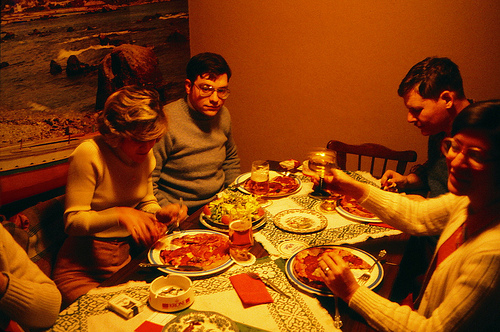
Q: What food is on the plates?
A: Pizza.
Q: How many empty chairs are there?
A: 1.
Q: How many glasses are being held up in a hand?
A: 1.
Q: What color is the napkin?
A: Red.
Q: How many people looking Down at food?
A: 2.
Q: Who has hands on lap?
A: Man in glasses.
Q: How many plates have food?
A: 5.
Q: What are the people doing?
A: Dining.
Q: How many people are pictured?
A: 5.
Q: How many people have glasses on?
A: Two.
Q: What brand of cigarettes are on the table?
A: Marlboro.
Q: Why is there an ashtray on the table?
A: For cigarette ashes/butts.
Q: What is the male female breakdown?
A: Two males, two females.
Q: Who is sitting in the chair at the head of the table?
A: No one.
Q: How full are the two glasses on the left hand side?
A: Three quarters.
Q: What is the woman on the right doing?
A: Raising her glass.